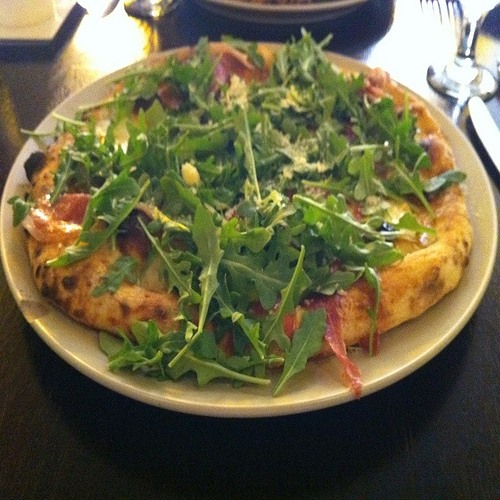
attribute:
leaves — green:
[101, 73, 396, 259]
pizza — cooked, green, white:
[40, 81, 474, 313]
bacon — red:
[319, 283, 348, 356]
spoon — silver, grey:
[427, 15, 500, 108]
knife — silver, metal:
[467, 106, 499, 175]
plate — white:
[8, 60, 470, 409]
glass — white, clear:
[130, 1, 187, 16]